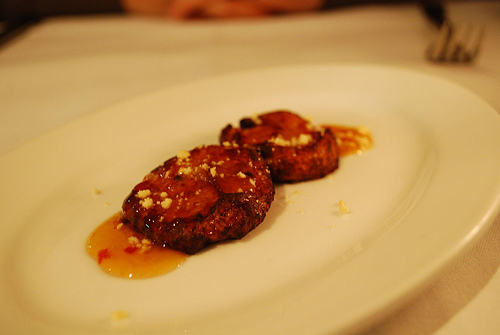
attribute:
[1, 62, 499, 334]
plate — white, clean, large, oval-shaped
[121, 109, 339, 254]
steak — sauteed, culinary, seasoned, small, plated, brown, black, fried, well-presented, slightly charred, in focus, well-cooked, cooked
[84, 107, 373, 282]
sauce — yellow, red, viscous, brown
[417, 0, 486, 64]
fork — stainless steel, dinner fork, blurry, blurred, metal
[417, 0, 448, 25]
handle — black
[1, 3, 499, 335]
table — white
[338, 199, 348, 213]
piece of cheese — small, yellow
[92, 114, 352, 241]
cheese — yellow, crumbled, white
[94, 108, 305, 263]
chili flakes — red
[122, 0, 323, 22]
hands — blurry, folded